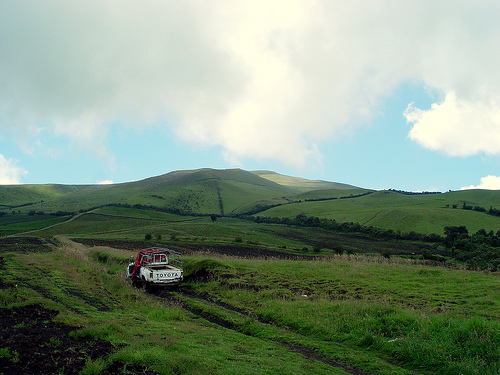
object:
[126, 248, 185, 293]
truck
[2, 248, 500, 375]
field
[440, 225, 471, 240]
trees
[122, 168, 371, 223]
mountain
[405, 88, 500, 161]
clouds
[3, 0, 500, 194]
sky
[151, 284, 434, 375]
tracks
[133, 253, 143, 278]
door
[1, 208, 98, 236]
road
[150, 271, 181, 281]
tailgate